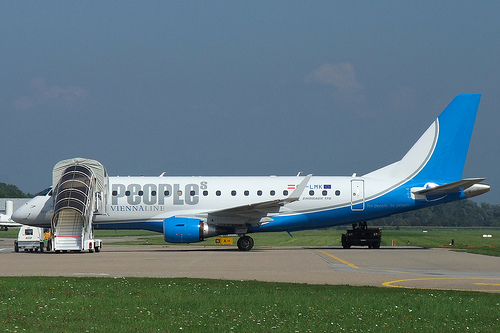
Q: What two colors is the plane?
A: Blue and white.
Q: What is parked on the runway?
A: An airplane.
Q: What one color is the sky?
A: Blue.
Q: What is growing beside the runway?
A: Grass.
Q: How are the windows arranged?
A: In a row.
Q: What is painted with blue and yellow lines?
A: Tarmac.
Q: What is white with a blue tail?
A: Plane.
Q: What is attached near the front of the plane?
A: Steps.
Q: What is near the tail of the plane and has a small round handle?
A: Door.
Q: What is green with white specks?
A: Grass.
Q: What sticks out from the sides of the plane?
A: Wings.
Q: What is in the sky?
A: Clouds.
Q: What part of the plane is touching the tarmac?
A: Wheels.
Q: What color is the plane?
A: Blue and white.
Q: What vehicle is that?
A: A plane.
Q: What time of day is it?
A: Daytime.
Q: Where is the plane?
A: On the tarmac.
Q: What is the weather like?
A: Clear.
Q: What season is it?
A: Spring.